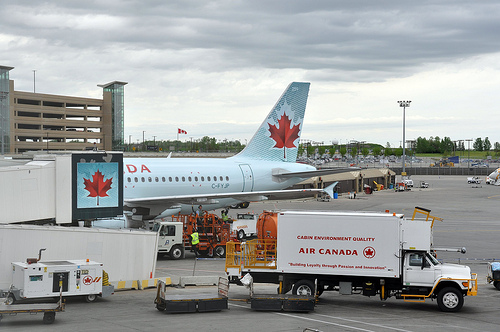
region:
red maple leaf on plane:
[262, 107, 301, 155]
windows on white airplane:
[119, 165, 239, 185]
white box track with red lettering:
[274, 207, 474, 305]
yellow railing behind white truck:
[224, 238, 277, 270]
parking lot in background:
[304, 140, 481, 169]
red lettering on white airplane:
[128, 157, 148, 175]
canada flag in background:
[178, 126, 193, 151]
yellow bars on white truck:
[396, 273, 480, 306]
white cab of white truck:
[405, 250, 464, 295]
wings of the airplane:
[140, 162, 392, 210]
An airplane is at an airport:
[28, 37, 478, 322]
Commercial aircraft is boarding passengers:
[16, 55, 456, 296]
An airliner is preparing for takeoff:
[45, 37, 460, 309]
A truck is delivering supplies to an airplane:
[265, 200, 480, 315]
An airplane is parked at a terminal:
[30, 55, 480, 310]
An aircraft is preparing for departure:
[23, 30, 478, 310]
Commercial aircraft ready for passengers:
[16, 62, 481, 308]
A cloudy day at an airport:
[17, 23, 482, 313]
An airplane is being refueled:
[20, 43, 481, 315]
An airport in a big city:
[22, 50, 479, 315]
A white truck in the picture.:
[273, 212, 473, 309]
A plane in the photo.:
[107, 79, 317, 199]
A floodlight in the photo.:
[387, 94, 417, 151]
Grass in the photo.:
[453, 149, 490, 159]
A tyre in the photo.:
[167, 244, 182, 258]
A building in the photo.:
[0, 66, 125, 151]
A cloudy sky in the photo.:
[154, 9, 296, 72]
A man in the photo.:
[186, 229, 201, 253]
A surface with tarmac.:
[448, 197, 485, 239]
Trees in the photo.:
[418, 136, 453, 155]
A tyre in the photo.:
[436, 288, 462, 313]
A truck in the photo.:
[276, 209, 475, 311]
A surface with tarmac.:
[115, 313, 249, 330]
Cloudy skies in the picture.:
[340, 4, 435, 76]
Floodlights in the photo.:
[397, 92, 416, 146]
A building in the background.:
[0, 66, 127, 149]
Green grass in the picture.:
[463, 147, 488, 156]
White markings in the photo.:
[322, 313, 397, 330]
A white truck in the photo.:
[276, 207, 478, 314]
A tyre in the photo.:
[441, 284, 466, 307]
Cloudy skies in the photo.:
[352, 17, 441, 65]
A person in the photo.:
[187, 229, 202, 254]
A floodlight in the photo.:
[395, 91, 413, 168]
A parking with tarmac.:
[448, 196, 487, 242]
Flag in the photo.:
[170, 123, 190, 141]